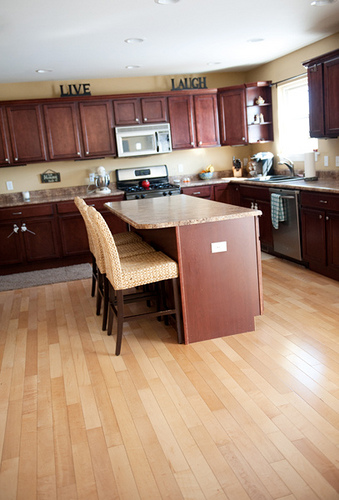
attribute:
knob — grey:
[77, 152, 80, 155]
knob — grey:
[134, 117, 139, 120]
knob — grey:
[318, 213, 322, 218]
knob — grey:
[324, 214, 329, 220]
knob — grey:
[198, 140, 203, 145]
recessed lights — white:
[115, 24, 147, 73]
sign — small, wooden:
[39, 167, 60, 182]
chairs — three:
[59, 186, 183, 340]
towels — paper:
[298, 146, 317, 178]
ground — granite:
[296, 92, 311, 119]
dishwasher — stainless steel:
[266, 186, 302, 264]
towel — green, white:
[268, 193, 284, 224]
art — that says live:
[60, 75, 95, 103]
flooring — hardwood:
[243, 325, 301, 378]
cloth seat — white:
[260, 194, 290, 232]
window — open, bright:
[274, 80, 308, 146]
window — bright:
[264, 76, 323, 161]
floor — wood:
[154, 24, 244, 52]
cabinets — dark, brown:
[34, 107, 231, 179]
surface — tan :
[3, 256, 335, 498]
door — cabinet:
[43, 102, 81, 160]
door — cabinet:
[111, 95, 142, 126]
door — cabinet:
[193, 91, 220, 148]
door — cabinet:
[301, 198, 326, 272]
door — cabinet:
[324, 203, 336, 279]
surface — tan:
[104, 195, 262, 231]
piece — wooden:
[58, 84, 91, 96]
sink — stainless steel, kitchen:
[239, 173, 304, 183]